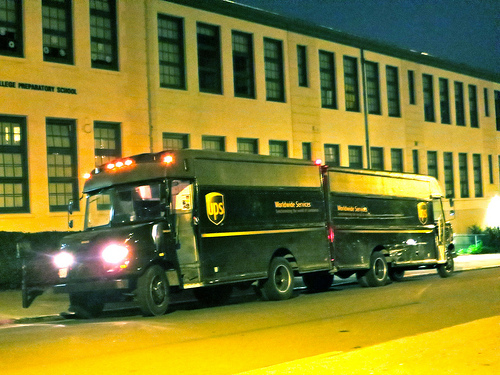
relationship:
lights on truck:
[97, 239, 139, 263] [72, 144, 328, 291]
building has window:
[59, 25, 475, 169] [190, 20, 238, 103]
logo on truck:
[202, 193, 240, 226] [72, 144, 328, 291]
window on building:
[190, 20, 238, 103] [59, 25, 475, 169]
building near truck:
[59, 25, 475, 169] [72, 144, 328, 291]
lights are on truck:
[97, 239, 139, 263] [72, 144, 328, 291]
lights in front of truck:
[97, 239, 139, 263] [72, 144, 328, 291]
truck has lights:
[72, 144, 328, 291] [97, 239, 139, 263]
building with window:
[59, 25, 475, 169] [190, 20, 238, 103]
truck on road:
[72, 144, 328, 291] [232, 312, 310, 337]